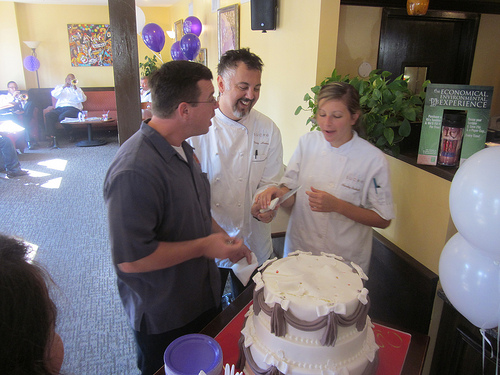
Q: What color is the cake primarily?
A: White.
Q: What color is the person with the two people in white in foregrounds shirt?
A: Dark gray.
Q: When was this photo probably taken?
A: Daytime.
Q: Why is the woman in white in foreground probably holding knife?
A: To cut cake.